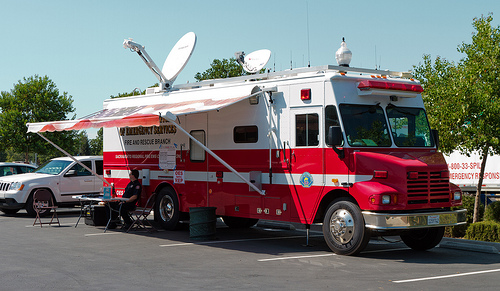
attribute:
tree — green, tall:
[411, 11, 499, 225]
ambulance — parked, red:
[23, 30, 467, 256]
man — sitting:
[105, 167, 141, 232]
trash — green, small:
[186, 204, 216, 240]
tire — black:
[320, 197, 370, 256]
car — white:
[0, 153, 102, 215]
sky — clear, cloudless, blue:
[1, 2, 500, 140]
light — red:
[301, 89, 312, 102]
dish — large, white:
[120, 31, 199, 92]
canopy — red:
[23, 91, 261, 134]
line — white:
[392, 269, 499, 284]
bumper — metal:
[360, 208, 470, 232]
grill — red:
[403, 165, 453, 210]